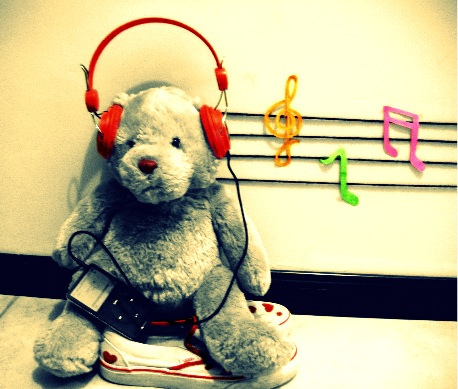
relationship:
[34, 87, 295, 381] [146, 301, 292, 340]
teddy bear sitting on shoe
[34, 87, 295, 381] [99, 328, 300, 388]
teddy bear sitting on shoe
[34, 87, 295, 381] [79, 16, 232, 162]
teddy bear wearing headphones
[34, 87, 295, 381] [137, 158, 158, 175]
teddy bear has nose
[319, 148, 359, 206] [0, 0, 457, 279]
music note hanging on wall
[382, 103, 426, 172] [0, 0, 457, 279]
music note hanging on wall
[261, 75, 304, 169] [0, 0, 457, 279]
music symbol hanging on wall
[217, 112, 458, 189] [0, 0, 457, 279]
music symbol hanging on wall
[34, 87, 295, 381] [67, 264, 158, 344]
teddy bear holding ipod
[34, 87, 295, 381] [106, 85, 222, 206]
teddy bear has head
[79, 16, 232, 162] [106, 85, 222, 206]
headphones worn on head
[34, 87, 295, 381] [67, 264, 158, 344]
teddy bear has ipod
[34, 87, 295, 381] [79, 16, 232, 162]
teddy bear wears headphones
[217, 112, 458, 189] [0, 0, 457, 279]
music symbol hangs on wall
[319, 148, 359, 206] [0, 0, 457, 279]
music note hangs on wall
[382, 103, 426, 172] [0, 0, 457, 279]
music note hangs on wall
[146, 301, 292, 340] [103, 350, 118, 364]
shoe has heart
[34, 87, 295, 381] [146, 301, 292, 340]
teddy bear sitting over shoe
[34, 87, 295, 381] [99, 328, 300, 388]
teddy bear sitting over shoe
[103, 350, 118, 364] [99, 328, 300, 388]
heart decorating shoe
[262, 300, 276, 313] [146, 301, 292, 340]
heart decorating shoe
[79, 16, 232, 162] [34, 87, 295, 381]
headphones worn by teddy bear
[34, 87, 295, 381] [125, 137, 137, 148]
teddy bear has eye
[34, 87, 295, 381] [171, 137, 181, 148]
teddy bear has eye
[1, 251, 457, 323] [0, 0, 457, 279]
border at bottom of wall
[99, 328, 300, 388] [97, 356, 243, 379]
shoe has stripe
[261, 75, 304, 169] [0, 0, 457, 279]
music symbol mounted on wall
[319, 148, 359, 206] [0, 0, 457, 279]
music note mounted on wall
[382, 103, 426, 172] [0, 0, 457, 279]
music note mounted on wall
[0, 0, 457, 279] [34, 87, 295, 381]
wall behind teddy bear